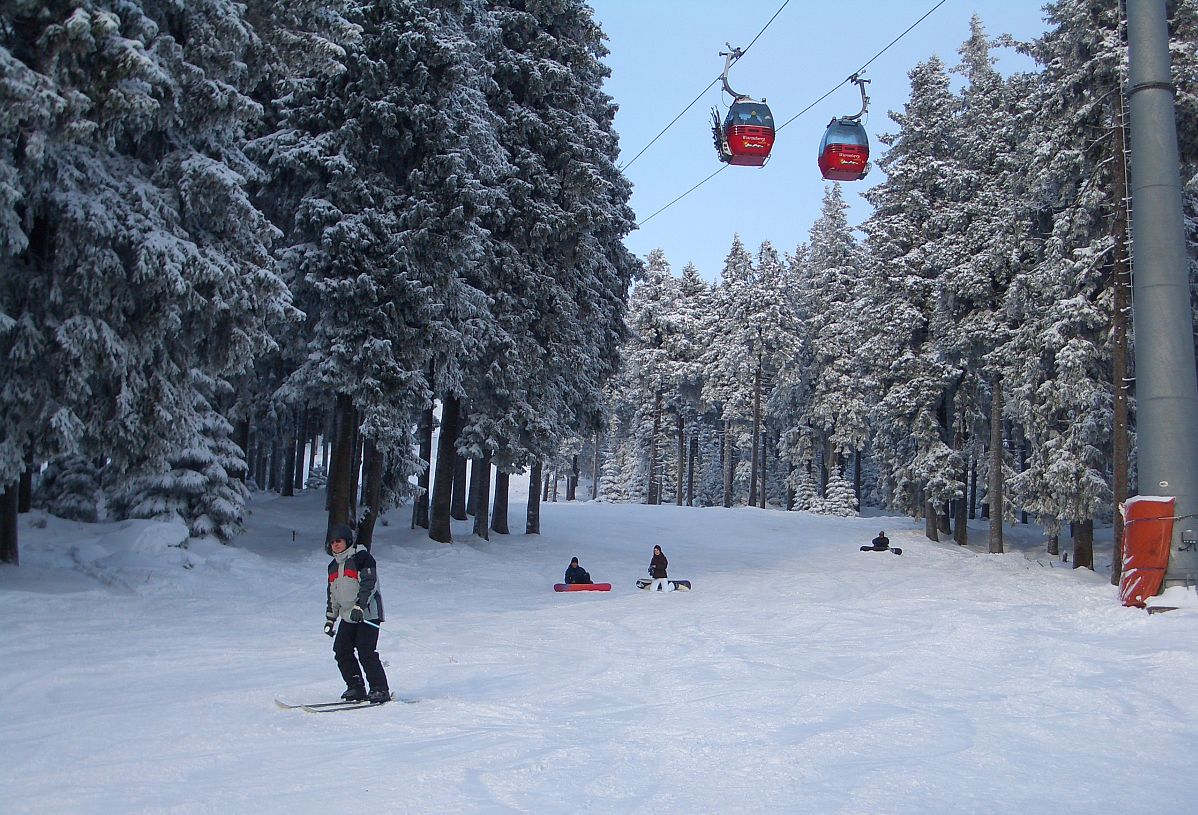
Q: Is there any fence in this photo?
A: No, there are no fences.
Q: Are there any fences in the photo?
A: No, there are no fences.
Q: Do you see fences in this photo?
A: No, there are no fences.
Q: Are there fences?
A: No, there are no fences.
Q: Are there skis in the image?
A: Yes, there are skis.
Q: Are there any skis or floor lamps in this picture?
A: Yes, there are skis.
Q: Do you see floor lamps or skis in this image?
A: Yes, there are skis.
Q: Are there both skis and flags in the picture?
A: No, there are skis but no flags.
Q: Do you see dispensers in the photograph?
A: No, there are no dispensers.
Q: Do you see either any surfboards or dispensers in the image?
A: No, there are no dispensers or surfboards.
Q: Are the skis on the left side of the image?
A: Yes, the skis are on the left of the image.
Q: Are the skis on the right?
A: No, the skis are on the left of the image.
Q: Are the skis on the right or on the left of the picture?
A: The skis are on the left of the image.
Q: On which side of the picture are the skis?
A: The skis are on the left of the image.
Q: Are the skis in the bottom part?
A: Yes, the skis are in the bottom of the image.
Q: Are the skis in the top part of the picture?
A: No, the skis are in the bottom of the image.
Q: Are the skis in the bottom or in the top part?
A: The skis are in the bottom of the image.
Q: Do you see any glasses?
A: No, there are no glasses.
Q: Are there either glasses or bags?
A: No, there are no glasses or bags.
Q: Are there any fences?
A: No, there are no fences.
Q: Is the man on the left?
A: Yes, the man is on the left of the image.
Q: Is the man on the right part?
A: No, the man is on the left of the image.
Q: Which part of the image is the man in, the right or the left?
A: The man is on the left of the image.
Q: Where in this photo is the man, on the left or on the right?
A: The man is on the left of the image.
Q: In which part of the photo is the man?
A: The man is on the left of the image.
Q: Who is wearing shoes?
A: The man is wearing shoes.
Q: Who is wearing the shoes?
A: The man is wearing shoes.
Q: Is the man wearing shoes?
A: Yes, the man is wearing shoes.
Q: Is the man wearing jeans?
A: No, the man is wearing shoes.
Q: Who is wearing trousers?
A: The man is wearing trousers.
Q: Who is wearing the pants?
A: The man is wearing trousers.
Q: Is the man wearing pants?
A: Yes, the man is wearing pants.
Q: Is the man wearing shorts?
A: No, the man is wearing pants.